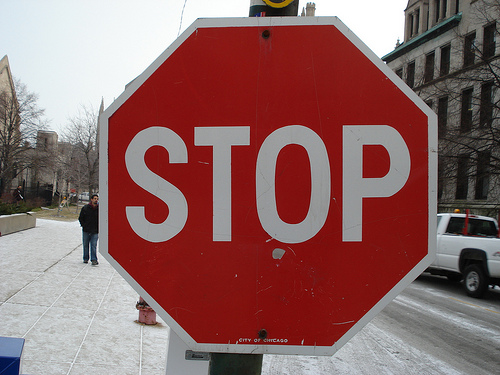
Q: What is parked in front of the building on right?
A: Truck.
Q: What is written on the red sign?
A: STOP.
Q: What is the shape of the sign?
A: Hexagon.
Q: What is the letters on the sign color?
A: White.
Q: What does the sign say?
A: STOP.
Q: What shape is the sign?
A: Octagon.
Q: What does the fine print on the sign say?
A: CITY OF CHICAGO.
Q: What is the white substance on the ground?
A: Snow.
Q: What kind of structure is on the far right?
A: A building.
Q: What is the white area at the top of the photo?
A: The sky.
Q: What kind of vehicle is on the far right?
A: A pickup truck.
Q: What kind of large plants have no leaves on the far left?
A: Trees.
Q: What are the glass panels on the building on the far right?
A: Windows.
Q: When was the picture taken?
A: Daytime.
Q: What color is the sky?
A: White.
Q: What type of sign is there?
A: A stop sign.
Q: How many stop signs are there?
A: One.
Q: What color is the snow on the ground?
A: White.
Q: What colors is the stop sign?
A: Red and white.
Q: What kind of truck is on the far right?
A: A pickup truck.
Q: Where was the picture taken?
A: In a city.